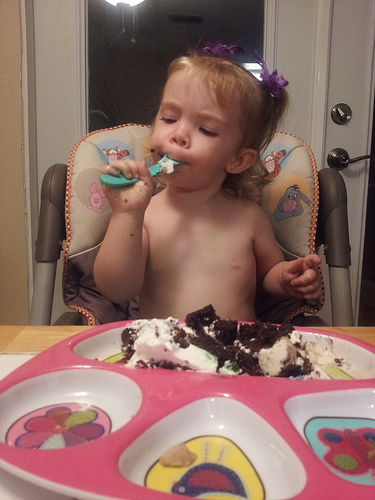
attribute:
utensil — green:
[112, 139, 190, 207]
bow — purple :
[196, 32, 312, 96]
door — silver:
[19, 0, 373, 330]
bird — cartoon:
[170, 442, 249, 498]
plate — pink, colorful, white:
[1, 317, 373, 499]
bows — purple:
[255, 54, 289, 100]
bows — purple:
[201, 39, 243, 57]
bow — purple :
[250, 53, 288, 95]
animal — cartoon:
[269, 182, 311, 222]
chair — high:
[35, 105, 360, 328]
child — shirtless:
[88, 36, 334, 321]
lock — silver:
[329, 99, 353, 126]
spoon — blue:
[100, 154, 183, 188]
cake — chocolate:
[117, 301, 316, 376]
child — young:
[117, 75, 315, 318]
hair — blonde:
[170, 39, 288, 154]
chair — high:
[38, 126, 358, 327]